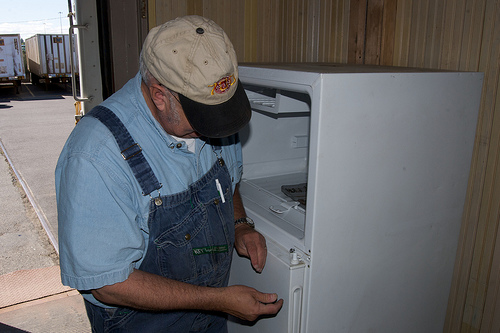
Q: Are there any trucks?
A: Yes, there are trucks.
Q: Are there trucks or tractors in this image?
A: Yes, there are trucks.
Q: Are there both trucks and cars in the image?
A: No, there are trucks but no cars.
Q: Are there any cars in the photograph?
A: No, there are no cars.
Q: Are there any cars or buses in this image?
A: No, there are no cars or buses.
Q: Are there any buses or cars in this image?
A: No, there are no cars or buses.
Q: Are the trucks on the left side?
A: Yes, the trucks are on the left of the image.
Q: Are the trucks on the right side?
A: No, the trucks are on the left of the image.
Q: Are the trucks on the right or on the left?
A: The trucks are on the left of the image.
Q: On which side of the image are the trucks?
A: The trucks are on the left of the image.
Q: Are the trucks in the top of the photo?
A: Yes, the trucks are in the top of the image.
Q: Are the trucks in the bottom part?
A: No, the trucks are in the top of the image.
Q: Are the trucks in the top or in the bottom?
A: The trucks are in the top of the image.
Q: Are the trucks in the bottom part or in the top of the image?
A: The trucks are in the top of the image.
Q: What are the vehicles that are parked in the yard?
A: The vehicles are trucks.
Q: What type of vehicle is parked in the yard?
A: The vehicles are trucks.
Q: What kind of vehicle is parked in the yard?
A: The vehicles are trucks.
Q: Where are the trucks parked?
A: The trucks are parked in the yard.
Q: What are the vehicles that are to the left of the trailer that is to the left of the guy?
A: The vehicles are trucks.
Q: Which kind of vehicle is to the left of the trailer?
A: The vehicles are trucks.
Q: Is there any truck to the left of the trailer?
A: Yes, there are trucks to the left of the trailer.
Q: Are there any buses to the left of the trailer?
A: No, there are trucks to the left of the trailer.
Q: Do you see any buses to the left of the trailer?
A: No, there are trucks to the left of the trailer.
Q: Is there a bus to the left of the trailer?
A: No, there are trucks to the left of the trailer.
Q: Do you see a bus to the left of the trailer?
A: No, there are trucks to the left of the trailer.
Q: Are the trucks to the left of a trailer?
A: Yes, the trucks are to the left of a trailer.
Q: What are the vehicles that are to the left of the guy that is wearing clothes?
A: The vehicles are trucks.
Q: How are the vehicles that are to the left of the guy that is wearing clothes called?
A: The vehicles are trucks.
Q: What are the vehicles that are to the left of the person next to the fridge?
A: The vehicles are trucks.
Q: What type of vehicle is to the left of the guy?
A: The vehicles are trucks.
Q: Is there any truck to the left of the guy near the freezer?
A: Yes, there are trucks to the left of the guy.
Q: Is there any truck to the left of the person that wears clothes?
A: Yes, there are trucks to the left of the guy.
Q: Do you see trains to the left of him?
A: No, there are trucks to the left of the guy.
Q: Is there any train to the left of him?
A: No, there are trucks to the left of the guy.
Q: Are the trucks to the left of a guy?
A: Yes, the trucks are to the left of a guy.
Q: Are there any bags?
A: No, there are no bags.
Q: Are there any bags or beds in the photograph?
A: No, there are no bags or beds.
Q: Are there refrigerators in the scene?
A: Yes, there is a refrigerator.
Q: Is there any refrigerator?
A: Yes, there is a refrigerator.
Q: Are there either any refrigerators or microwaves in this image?
A: Yes, there is a refrigerator.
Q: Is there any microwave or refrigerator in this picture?
A: Yes, there is a refrigerator.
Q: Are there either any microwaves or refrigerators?
A: Yes, there is a refrigerator.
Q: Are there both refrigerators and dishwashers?
A: No, there is a refrigerator but no dishwashers.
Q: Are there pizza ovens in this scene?
A: No, there are no pizza ovens.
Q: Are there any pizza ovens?
A: No, there are no pizza ovens.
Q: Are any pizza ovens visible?
A: No, there are no pizza ovens.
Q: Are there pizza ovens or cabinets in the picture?
A: No, there are no pizza ovens or cabinets.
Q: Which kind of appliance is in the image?
A: The appliance is a refrigerator.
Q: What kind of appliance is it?
A: The appliance is a refrigerator.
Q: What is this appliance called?
A: That is a refrigerator.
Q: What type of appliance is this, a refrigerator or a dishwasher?
A: That is a refrigerator.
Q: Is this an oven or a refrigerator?
A: This is a refrigerator.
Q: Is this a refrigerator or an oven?
A: This is a refrigerator.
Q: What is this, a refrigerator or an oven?
A: This is a refrigerator.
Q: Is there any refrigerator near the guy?
A: Yes, there is a refrigerator near the guy.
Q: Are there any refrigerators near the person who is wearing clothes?
A: Yes, there is a refrigerator near the guy.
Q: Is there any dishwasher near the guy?
A: No, there is a refrigerator near the guy.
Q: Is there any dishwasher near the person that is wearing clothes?
A: No, there is a refrigerator near the guy.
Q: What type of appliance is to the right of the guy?
A: The appliance is a refrigerator.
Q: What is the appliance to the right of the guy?
A: The appliance is a refrigerator.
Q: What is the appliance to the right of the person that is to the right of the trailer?
A: The appliance is a refrigerator.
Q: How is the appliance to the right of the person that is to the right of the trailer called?
A: The appliance is a refrigerator.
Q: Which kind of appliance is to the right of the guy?
A: The appliance is a refrigerator.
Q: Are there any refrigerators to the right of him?
A: Yes, there is a refrigerator to the right of the guy.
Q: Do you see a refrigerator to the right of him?
A: Yes, there is a refrigerator to the right of the guy.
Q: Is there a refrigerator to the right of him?
A: Yes, there is a refrigerator to the right of the guy.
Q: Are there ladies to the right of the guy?
A: No, there is a refrigerator to the right of the guy.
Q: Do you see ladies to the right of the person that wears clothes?
A: No, there is a refrigerator to the right of the guy.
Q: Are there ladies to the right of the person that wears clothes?
A: No, there is a refrigerator to the right of the guy.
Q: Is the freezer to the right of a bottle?
A: No, the freezer is to the right of a guy.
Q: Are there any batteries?
A: No, there are no batteries.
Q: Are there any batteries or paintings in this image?
A: No, there are no batteries or paintings.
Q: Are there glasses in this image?
A: No, there are no glasses.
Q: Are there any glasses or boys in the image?
A: No, there are no glasses or boys.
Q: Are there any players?
A: No, there are no players.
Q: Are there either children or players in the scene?
A: No, there are no players or children.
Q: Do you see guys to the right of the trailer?
A: Yes, there is a guy to the right of the trailer.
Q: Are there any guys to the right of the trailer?
A: Yes, there is a guy to the right of the trailer.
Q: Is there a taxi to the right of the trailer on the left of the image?
A: No, there is a guy to the right of the trailer.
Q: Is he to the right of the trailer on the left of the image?
A: Yes, the guy is to the right of the trailer.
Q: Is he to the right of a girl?
A: No, the guy is to the right of the trailer.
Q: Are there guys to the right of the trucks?
A: Yes, there is a guy to the right of the trucks.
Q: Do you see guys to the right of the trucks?
A: Yes, there is a guy to the right of the trucks.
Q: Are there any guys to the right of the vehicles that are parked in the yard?
A: Yes, there is a guy to the right of the trucks.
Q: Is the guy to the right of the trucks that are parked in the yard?
A: Yes, the guy is to the right of the trucks.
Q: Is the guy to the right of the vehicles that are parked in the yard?
A: Yes, the guy is to the right of the trucks.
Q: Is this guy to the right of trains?
A: No, the guy is to the right of the trucks.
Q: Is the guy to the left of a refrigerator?
A: Yes, the guy is to the left of a refrigerator.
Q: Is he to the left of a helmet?
A: No, the guy is to the left of a refrigerator.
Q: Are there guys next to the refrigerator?
A: Yes, there is a guy next to the refrigerator.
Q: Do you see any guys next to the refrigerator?
A: Yes, there is a guy next to the refrigerator.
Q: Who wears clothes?
A: The guy wears clothes.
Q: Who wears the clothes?
A: The guy wears clothes.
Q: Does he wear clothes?
A: Yes, the guy wears clothes.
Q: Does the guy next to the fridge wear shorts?
A: No, the guy wears clothes.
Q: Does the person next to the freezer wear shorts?
A: No, the guy wears clothes.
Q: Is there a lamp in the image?
A: No, there are no lamps.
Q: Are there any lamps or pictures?
A: No, there are no lamps or pictures.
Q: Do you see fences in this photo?
A: No, there are no fences.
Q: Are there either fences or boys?
A: No, there are no fences or boys.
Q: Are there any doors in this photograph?
A: Yes, there is a door.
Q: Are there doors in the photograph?
A: Yes, there is a door.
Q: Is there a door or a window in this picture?
A: Yes, there is a door.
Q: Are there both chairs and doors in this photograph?
A: No, there is a door but no chairs.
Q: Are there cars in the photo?
A: No, there are no cars.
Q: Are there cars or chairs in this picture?
A: No, there are no cars or chairs.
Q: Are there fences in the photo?
A: No, there are no fences.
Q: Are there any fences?
A: No, there are no fences.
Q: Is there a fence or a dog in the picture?
A: No, there are no fences or dogs.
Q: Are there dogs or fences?
A: No, there are no fences or dogs.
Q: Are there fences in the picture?
A: No, there are no fences.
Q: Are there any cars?
A: No, there are no cars.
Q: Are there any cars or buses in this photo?
A: No, there are no cars or buses.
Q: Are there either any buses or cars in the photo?
A: No, there are no cars or buses.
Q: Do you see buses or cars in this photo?
A: No, there are no cars or buses.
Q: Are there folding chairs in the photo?
A: No, there are no folding chairs.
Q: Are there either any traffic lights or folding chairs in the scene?
A: No, there are no folding chairs or traffic lights.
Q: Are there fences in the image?
A: No, there are no fences.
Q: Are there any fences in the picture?
A: No, there are no fences.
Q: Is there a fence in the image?
A: No, there are no fences.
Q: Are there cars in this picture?
A: No, there are no cars.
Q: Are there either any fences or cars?
A: No, there are no cars or fences.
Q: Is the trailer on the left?
A: Yes, the trailer is on the left of the image.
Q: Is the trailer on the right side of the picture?
A: No, the trailer is on the left of the image.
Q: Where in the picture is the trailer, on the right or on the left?
A: The trailer is on the left of the image.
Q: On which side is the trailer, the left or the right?
A: The trailer is on the left of the image.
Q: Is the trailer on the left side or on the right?
A: The trailer is on the left of the image.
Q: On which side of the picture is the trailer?
A: The trailer is on the left of the image.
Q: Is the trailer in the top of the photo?
A: Yes, the trailer is in the top of the image.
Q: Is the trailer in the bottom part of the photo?
A: No, the trailer is in the top of the image.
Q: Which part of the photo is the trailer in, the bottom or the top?
A: The trailer is in the top of the image.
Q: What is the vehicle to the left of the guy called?
A: The vehicle is a trailer.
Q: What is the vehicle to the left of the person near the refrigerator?
A: The vehicle is a trailer.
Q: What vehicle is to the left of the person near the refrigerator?
A: The vehicle is a trailer.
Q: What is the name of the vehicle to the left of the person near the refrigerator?
A: The vehicle is a trailer.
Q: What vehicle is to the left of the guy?
A: The vehicle is a trailer.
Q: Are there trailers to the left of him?
A: Yes, there is a trailer to the left of the guy.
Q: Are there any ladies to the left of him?
A: No, there is a trailer to the left of the guy.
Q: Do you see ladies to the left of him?
A: No, there is a trailer to the left of the guy.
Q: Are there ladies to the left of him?
A: No, there is a trailer to the left of the guy.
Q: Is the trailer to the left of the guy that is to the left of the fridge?
A: Yes, the trailer is to the left of the guy.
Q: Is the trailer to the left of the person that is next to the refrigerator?
A: Yes, the trailer is to the left of the guy.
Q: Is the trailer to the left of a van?
A: No, the trailer is to the left of the guy.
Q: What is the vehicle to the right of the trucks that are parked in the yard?
A: The vehicle is a trailer.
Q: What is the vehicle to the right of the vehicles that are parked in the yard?
A: The vehicle is a trailer.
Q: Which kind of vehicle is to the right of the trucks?
A: The vehicle is a trailer.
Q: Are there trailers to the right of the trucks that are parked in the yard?
A: Yes, there is a trailer to the right of the trucks.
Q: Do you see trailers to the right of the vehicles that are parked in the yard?
A: Yes, there is a trailer to the right of the trucks.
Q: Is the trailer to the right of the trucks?
A: Yes, the trailer is to the right of the trucks.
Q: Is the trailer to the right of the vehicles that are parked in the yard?
A: Yes, the trailer is to the right of the trucks.